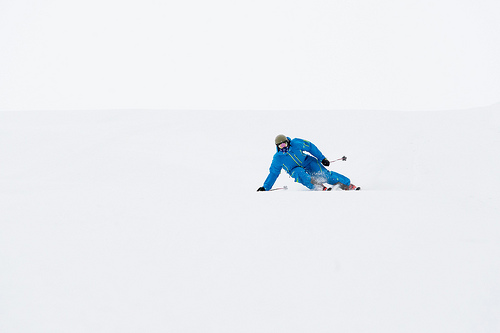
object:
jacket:
[259, 136, 354, 191]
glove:
[322, 159, 330, 166]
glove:
[257, 186, 266, 191]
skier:
[257, 135, 360, 192]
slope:
[0, 107, 490, 333]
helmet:
[275, 134, 290, 149]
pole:
[330, 158, 346, 163]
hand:
[322, 159, 330, 167]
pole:
[267, 187, 287, 191]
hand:
[257, 187, 266, 191]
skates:
[340, 184, 361, 191]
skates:
[315, 184, 333, 193]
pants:
[289, 157, 351, 190]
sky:
[0, 0, 497, 107]